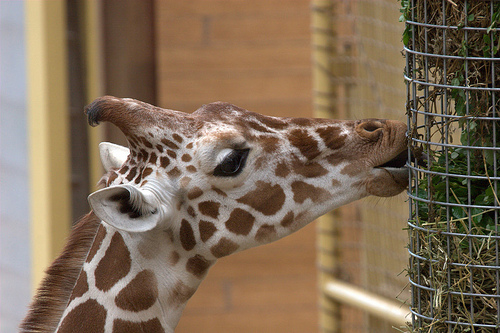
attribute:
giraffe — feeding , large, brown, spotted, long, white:
[26, 93, 425, 332]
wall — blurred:
[155, 0, 365, 330]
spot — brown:
[315, 122, 349, 150]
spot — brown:
[284, 123, 324, 167]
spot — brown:
[275, 154, 291, 179]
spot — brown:
[290, 177, 330, 207]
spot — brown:
[281, 207, 298, 225]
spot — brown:
[235, 175, 287, 215]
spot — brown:
[223, 203, 257, 238]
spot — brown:
[195, 200, 221, 220]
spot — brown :
[179, 219, 197, 256]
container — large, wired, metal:
[401, 0, 499, 331]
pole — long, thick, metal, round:
[324, 278, 413, 331]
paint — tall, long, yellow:
[24, 1, 70, 305]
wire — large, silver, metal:
[402, 1, 499, 331]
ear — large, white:
[85, 182, 174, 233]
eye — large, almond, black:
[211, 147, 251, 177]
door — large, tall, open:
[73, 3, 317, 332]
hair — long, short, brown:
[17, 211, 99, 331]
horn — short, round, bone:
[83, 94, 176, 146]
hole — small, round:
[362, 123, 380, 132]